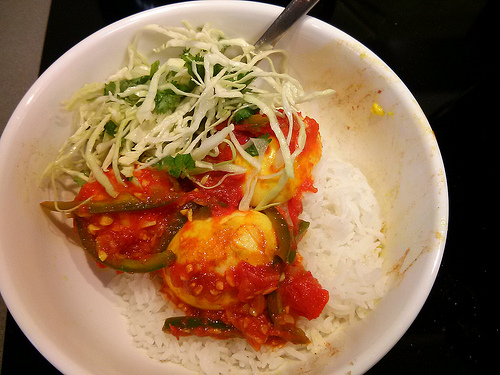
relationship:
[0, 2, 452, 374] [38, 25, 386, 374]
bowl filled with food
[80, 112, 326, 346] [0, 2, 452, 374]
sauce in bowl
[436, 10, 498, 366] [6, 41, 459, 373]
black mat under plate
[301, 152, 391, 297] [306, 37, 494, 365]
rice on plate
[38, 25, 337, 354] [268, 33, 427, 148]
food in bowl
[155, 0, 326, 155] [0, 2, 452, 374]
utensil in bowl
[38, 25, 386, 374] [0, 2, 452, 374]
food in bowl